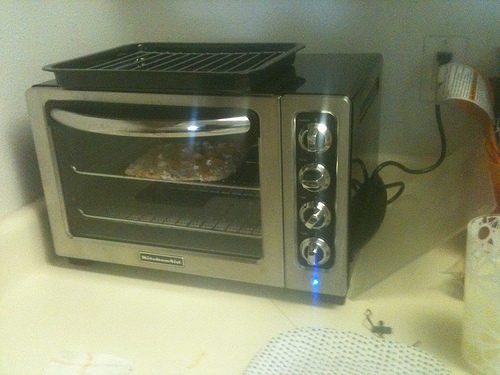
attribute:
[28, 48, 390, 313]
oven — toaster, square, silver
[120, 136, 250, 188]
pizza — cooking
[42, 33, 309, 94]
tray — black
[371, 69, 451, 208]
cord — plugged, black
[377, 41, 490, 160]
wall — white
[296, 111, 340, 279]
knobs — dials, silver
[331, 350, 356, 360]
dots — blue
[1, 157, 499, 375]
counter top — white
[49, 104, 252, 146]
handle — silver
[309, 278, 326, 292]
light — blue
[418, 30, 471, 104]
outlet — electrical